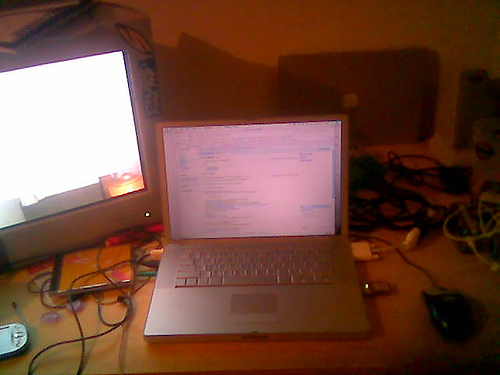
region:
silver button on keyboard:
[174, 279, 187, 288]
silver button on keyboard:
[185, 278, 197, 288]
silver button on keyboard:
[196, 274, 210, 285]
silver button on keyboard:
[208, 275, 223, 285]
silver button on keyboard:
[277, 272, 291, 284]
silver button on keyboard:
[290, 274, 303, 284]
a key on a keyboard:
[174, 275, 185, 290]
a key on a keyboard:
[185, 275, 202, 287]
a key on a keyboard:
[207, 278, 224, 293]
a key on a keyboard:
[314, 274, 326, 288]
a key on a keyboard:
[209, 271, 223, 278]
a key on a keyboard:
[176, 268, 203, 281]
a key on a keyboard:
[183, 255, 193, 265]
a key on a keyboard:
[193, 250, 202, 260]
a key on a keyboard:
[218, 263, 227, 268]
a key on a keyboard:
[247, 263, 255, 268]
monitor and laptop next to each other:
[3, 37, 380, 343]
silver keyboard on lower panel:
[142, 235, 372, 334]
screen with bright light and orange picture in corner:
[7, 52, 146, 232]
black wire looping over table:
[29, 225, 164, 370]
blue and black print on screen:
[159, 117, 345, 234]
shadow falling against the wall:
[152, 25, 299, 125]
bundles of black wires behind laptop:
[320, 144, 462, 254]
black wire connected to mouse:
[357, 229, 491, 354]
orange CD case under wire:
[49, 242, 136, 297]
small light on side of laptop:
[345, 275, 394, 297]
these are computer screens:
[32, 20, 480, 322]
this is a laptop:
[148, 141, 426, 282]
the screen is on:
[161, 113, 359, 247]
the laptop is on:
[164, 228, 352, 348]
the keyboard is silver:
[200, 230, 281, 284]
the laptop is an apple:
[175, 174, 425, 366]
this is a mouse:
[404, 268, 489, 359]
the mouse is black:
[427, 248, 498, 336]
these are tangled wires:
[371, 153, 482, 264]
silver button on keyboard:
[176, 256, 194, 265]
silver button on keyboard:
[175, 261, 195, 270]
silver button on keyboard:
[176, 270, 201, 277]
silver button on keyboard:
[176, 277, 186, 288]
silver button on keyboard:
[186, 277, 197, 286]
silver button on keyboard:
[207, 275, 224, 285]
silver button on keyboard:
[221, 273, 276, 285]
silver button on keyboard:
[289, 275, 301, 285]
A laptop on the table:
[150, 106, 356, 334]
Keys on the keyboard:
[172, 237, 340, 290]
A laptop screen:
[165, 117, 340, 247]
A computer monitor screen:
[11, 65, 141, 217]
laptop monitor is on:
[154, 112, 350, 244]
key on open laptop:
[172, 277, 186, 288]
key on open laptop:
[184, 277, 197, 287]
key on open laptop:
[196, 274, 209, 285]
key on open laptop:
[276, 274, 292, 284]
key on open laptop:
[176, 271, 202, 278]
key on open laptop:
[289, 272, 304, 283]